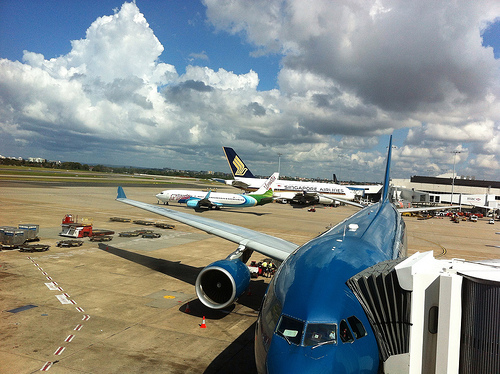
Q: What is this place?
A: Airport.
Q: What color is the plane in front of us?
A: Blue.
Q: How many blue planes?
A: One.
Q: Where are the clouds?
A: In the sky.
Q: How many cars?
A: None.